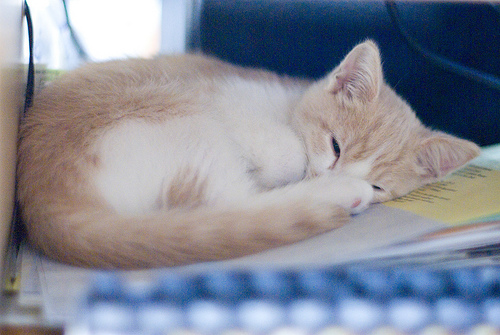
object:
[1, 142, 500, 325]
paper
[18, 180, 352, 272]
tail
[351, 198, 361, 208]
spot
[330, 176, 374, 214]
cat foot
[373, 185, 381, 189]
eye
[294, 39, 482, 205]
head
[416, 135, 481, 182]
cat ear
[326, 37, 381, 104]
cat ear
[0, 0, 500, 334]
surface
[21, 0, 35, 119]
black cord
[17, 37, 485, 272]
cat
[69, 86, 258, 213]
belly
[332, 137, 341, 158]
eye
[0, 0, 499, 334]
background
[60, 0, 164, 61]
window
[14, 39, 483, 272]
fur